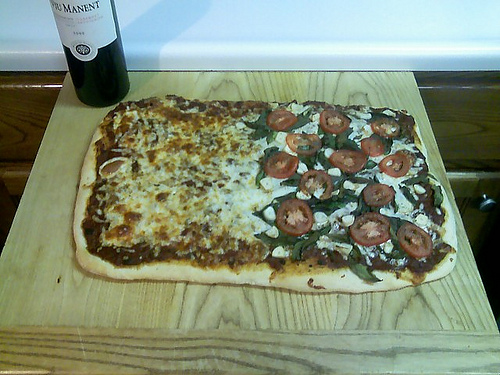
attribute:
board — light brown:
[78, 90, 493, 331]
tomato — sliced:
[301, 170, 333, 203]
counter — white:
[0, 0, 500, 72]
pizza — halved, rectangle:
[75, 96, 450, 288]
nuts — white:
[265, 103, 435, 257]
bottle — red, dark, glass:
[50, 0, 132, 108]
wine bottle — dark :
[56, 7, 140, 100]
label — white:
[49, 0, 118, 65]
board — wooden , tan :
[2, 69, 499, 372]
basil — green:
[290, 108, 310, 128]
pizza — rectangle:
[71, 95, 481, 297]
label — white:
[50, 0, 117, 60]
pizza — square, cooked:
[59, 95, 457, 302]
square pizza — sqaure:
[82, 100, 444, 264]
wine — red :
[45, 3, 134, 118]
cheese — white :
[110, 104, 436, 267]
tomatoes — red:
[264, 103, 430, 260]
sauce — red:
[83, 201, 113, 259]